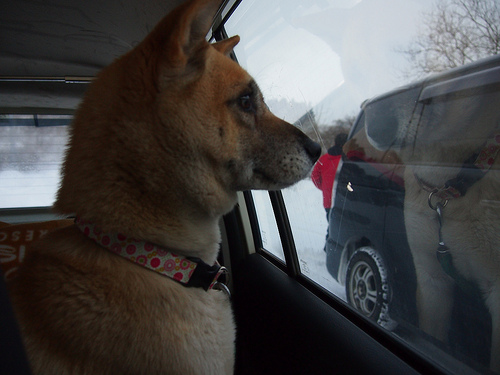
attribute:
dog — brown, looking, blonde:
[2, 4, 320, 374]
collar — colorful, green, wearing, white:
[66, 208, 235, 296]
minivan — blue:
[326, 62, 496, 348]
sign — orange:
[2, 219, 73, 265]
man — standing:
[312, 130, 348, 236]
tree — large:
[417, 3, 498, 75]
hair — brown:
[79, 88, 217, 210]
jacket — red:
[313, 147, 342, 212]